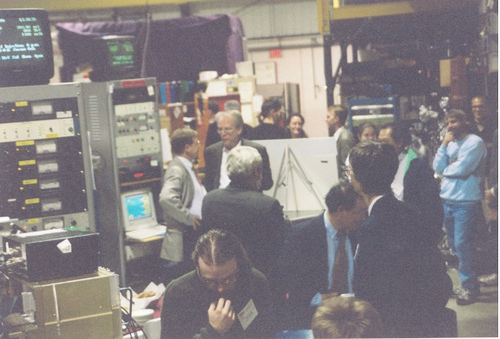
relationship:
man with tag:
[161, 229, 275, 337] [235, 298, 260, 331]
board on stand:
[242, 138, 341, 221] [272, 146, 326, 218]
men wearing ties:
[157, 93, 499, 338] [224, 150, 238, 179]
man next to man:
[161, 229, 275, 337] [201, 146, 289, 284]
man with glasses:
[161, 229, 275, 337] [200, 274, 242, 288]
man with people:
[161, 229, 275, 337] [147, 96, 499, 337]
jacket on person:
[351, 143, 456, 338] [354, 196, 454, 338]